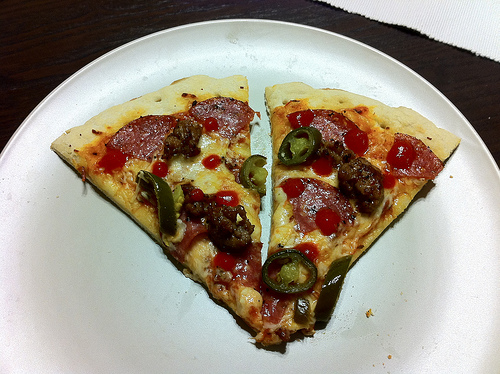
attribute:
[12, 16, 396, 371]
plate — part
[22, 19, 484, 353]
plate — part, grey, white, half-empty, circular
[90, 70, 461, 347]
pizza — sliced, brown, triangular, cooked, thin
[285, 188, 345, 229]
pepperoni — red, round, sliced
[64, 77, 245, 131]
crust — baked, sliced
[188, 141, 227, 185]
cheese — yellow, melted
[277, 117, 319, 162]
pepper — round, green, sliced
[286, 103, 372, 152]
tomato — red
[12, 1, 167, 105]
mat — black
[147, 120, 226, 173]
meat — dark brown